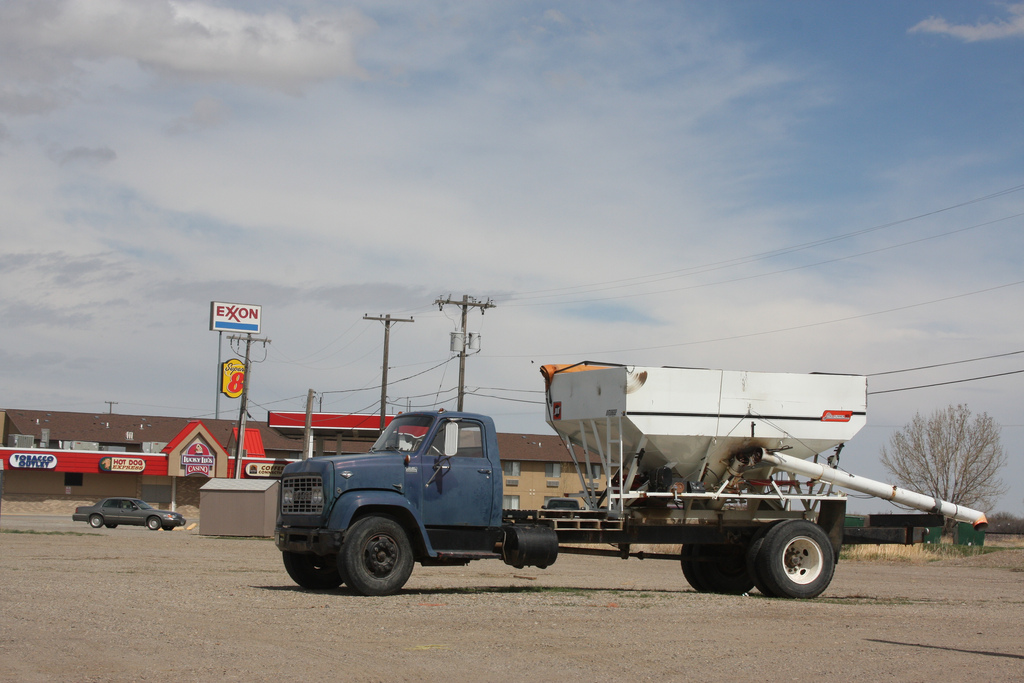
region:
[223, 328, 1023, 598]
a truck for hauling grain or feed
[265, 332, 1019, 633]
a farm truck parked in a lot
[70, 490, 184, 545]
a large gold colored sedan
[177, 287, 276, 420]
a sign for gas station and motel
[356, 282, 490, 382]
two tall power poles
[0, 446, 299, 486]
a bunch of signs on a building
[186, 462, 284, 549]
a small supply shed in a parking lot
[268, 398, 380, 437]
red roof on a motel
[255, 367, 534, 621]
a farm truck with a blue cab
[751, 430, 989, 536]
chute to dispense grain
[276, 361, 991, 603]
blue truck with white container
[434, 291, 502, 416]
telephone pole with two transformers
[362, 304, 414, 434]
telephone pole next to red roof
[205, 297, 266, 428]
white sign with blue stripe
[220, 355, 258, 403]
yellow sign with red number 8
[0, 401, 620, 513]
beige building with brown roof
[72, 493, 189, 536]
dark gray car in front of building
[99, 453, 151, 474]
beige sign that says HOT DOG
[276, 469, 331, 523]
metal grill on front of truck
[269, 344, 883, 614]
a blue truck with white tank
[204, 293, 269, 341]
an exxon sign in the sky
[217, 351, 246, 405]
a Super 8 motel sign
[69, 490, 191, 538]
a silver car in the parking lot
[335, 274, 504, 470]
two telephone poles behind the truck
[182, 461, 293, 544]
a shed close to the car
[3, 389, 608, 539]
a brown hotel behind the building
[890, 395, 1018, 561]
a single leafless tree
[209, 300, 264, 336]
an exxon gas station sign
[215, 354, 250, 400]
a yellow sign with a red number eight on it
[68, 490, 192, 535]
a grey colored car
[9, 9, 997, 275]
a lot of clouds in the sky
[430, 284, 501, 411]
an electric pole with two grey containers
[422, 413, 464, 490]
the side mirror of the truck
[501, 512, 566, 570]
a black gas tank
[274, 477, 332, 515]
headlights on the front of a truck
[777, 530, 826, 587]
a white wheel of a tire